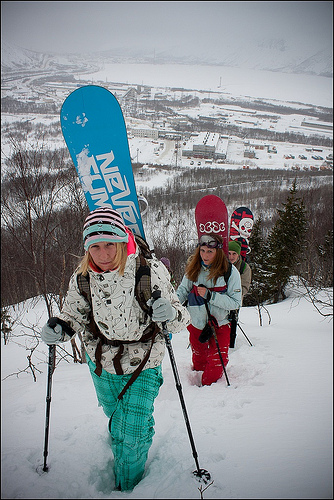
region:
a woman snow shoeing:
[59, 207, 186, 492]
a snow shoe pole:
[156, 313, 212, 485]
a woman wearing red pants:
[177, 194, 241, 385]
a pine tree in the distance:
[273, 183, 305, 299]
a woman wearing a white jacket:
[67, 205, 189, 491]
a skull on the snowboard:
[230, 217, 253, 241]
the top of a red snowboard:
[193, 193, 228, 236]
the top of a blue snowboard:
[59, 84, 139, 209]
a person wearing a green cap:
[228, 239, 241, 260]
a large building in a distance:
[182, 128, 228, 159]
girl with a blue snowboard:
[54, 85, 156, 273]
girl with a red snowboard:
[184, 191, 229, 273]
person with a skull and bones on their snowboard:
[226, 206, 254, 268]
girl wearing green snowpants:
[77, 347, 161, 491]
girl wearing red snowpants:
[182, 317, 231, 396]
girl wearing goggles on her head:
[196, 233, 217, 249]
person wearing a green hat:
[225, 240, 240, 263]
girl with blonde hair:
[71, 242, 125, 275]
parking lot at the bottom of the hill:
[259, 145, 332, 168]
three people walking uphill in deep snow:
[27, 198, 266, 498]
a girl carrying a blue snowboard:
[39, 85, 211, 490]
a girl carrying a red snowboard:
[176, 194, 242, 387]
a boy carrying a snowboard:
[228, 206, 252, 298]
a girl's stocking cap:
[83, 206, 130, 244]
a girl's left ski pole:
[150, 291, 210, 482]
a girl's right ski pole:
[40, 317, 58, 472]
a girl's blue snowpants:
[81, 355, 163, 490]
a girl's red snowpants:
[187, 321, 229, 384]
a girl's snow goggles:
[197, 234, 221, 247]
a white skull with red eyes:
[229, 214, 252, 245]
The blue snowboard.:
[62, 86, 147, 226]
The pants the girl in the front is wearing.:
[79, 366, 156, 486]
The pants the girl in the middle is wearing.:
[189, 319, 225, 385]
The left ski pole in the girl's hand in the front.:
[42, 335, 52, 475]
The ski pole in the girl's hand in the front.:
[162, 316, 217, 485]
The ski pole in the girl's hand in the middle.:
[207, 301, 233, 388]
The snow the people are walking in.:
[21, 332, 299, 498]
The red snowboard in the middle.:
[196, 198, 224, 245]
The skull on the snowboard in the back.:
[229, 217, 251, 239]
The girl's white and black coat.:
[59, 230, 179, 368]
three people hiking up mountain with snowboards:
[35, 212, 277, 486]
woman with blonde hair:
[73, 207, 137, 281]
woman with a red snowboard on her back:
[189, 193, 230, 373]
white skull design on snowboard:
[231, 215, 258, 246]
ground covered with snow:
[235, 374, 304, 478]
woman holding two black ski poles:
[22, 295, 196, 493]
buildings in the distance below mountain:
[132, 79, 313, 162]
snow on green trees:
[247, 249, 278, 298]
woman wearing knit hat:
[76, 201, 134, 251]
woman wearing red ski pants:
[188, 318, 233, 381]